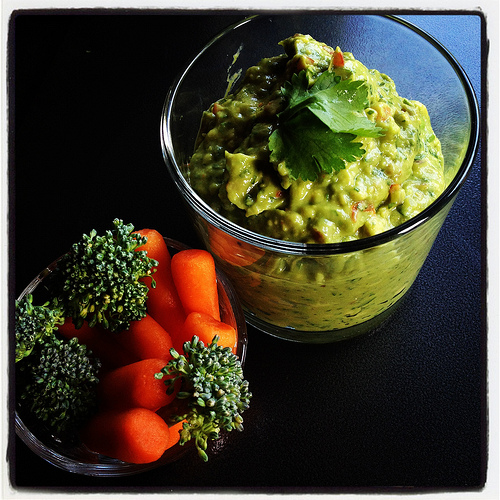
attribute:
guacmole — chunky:
[189, 27, 448, 335]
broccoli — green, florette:
[152, 332, 252, 460]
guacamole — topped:
[200, 27, 445, 335]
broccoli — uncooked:
[12, 213, 254, 492]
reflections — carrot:
[205, 221, 265, 271]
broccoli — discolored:
[44, 205, 162, 331]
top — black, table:
[17, 15, 466, 480]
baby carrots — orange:
[100, 223, 212, 465]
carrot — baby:
[166, 241, 224, 321]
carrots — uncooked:
[100, 351, 180, 472]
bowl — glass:
[138, 16, 482, 347]